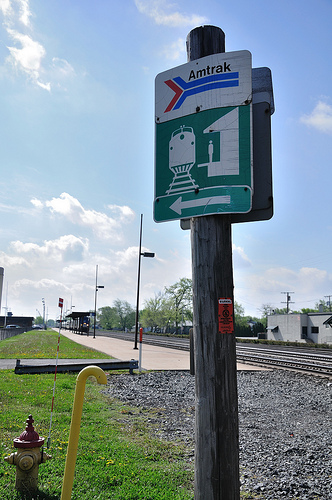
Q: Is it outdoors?
A: Yes, it is outdoors.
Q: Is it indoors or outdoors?
A: It is outdoors.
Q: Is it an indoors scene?
A: No, it is outdoors.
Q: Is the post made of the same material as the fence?
A: No, the post is made of wood and the fence is made of metal.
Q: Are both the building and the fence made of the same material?
A: No, the building is made of concrete and the fence is made of metal.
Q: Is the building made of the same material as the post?
A: No, the building is made of concrete and the post is made of wood.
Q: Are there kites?
A: No, there are no kites.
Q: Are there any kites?
A: No, there are no kites.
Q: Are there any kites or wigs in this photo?
A: No, there are no kites or wigs.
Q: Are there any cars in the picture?
A: No, there are no cars.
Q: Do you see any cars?
A: No, there are no cars.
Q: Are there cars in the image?
A: No, there are no cars.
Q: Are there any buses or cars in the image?
A: No, there are no cars or buses.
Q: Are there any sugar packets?
A: No, there are no sugar packets.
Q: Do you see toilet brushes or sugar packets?
A: No, there are no sugar packets or toilet brushes.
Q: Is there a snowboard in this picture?
A: No, there are no snowboards.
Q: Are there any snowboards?
A: No, there are no snowboards.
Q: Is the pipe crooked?
A: Yes, the pipe is crooked.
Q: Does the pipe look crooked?
A: Yes, the pipe is crooked.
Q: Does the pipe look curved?
A: Yes, the pipe is curved.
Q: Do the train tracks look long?
A: Yes, the train tracks are long.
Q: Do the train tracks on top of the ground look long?
A: Yes, the railroad tracks are long.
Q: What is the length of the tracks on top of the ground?
A: The tracks are long.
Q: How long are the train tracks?
A: The train tracks are long.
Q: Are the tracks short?
A: No, the tracks are long.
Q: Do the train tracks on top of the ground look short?
A: No, the train tracks are long.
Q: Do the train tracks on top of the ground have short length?
A: No, the train tracks are long.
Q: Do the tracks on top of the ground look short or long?
A: The tracks are long.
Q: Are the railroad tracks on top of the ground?
A: Yes, the railroad tracks are on top of the ground.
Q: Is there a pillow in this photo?
A: No, there are no pillows.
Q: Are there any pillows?
A: No, there are no pillows.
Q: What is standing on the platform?
A: The lamp post is standing on the platform.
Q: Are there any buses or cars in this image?
A: No, there are no cars or buses.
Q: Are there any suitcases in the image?
A: No, there are no suitcases.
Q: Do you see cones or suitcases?
A: No, there are no suitcases or cones.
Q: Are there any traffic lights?
A: No, there are no traffic lights.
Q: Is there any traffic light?
A: No, there are no traffic lights.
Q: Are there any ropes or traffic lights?
A: No, there are no traffic lights or ropes.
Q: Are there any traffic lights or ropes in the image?
A: No, there are no traffic lights or ropes.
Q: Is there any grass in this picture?
A: Yes, there is grass.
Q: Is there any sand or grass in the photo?
A: Yes, there is grass.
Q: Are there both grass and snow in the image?
A: No, there is grass but no snow.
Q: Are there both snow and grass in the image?
A: No, there is grass but no snow.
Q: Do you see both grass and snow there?
A: No, there is grass but no snow.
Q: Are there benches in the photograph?
A: No, there are no benches.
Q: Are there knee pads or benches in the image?
A: No, there are no benches or knee pads.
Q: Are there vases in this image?
A: No, there are no vases.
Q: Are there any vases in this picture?
A: No, there are no vases.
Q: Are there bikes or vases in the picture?
A: No, there are no vases or bikes.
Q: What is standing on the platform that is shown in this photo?
A: The street light is standing on the platform.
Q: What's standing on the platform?
A: The street light is standing on the platform.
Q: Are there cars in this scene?
A: No, there are no cars.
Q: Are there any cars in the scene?
A: No, there are no cars.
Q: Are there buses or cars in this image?
A: No, there are no cars or buses.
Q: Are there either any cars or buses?
A: No, there are no cars or buses.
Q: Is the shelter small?
A: Yes, the shelter is small.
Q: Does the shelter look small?
A: Yes, the shelter is small.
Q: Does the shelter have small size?
A: Yes, the shelter is small.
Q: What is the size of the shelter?
A: The shelter is small.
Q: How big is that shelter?
A: The shelter is small.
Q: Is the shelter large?
A: No, the shelter is small.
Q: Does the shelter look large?
A: No, the shelter is small.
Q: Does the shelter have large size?
A: No, the shelter is small.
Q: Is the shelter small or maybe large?
A: The shelter is small.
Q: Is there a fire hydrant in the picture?
A: Yes, there is a fire hydrant.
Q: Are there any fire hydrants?
A: Yes, there is a fire hydrant.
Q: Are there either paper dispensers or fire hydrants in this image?
A: Yes, there is a fire hydrant.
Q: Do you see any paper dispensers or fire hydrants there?
A: Yes, there is a fire hydrant.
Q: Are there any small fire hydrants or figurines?
A: Yes, there is a small fire hydrant.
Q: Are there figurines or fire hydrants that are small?
A: Yes, the fire hydrant is small.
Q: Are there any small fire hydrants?
A: Yes, there is a small fire hydrant.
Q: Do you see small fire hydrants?
A: Yes, there is a small fire hydrant.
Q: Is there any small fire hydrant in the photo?
A: Yes, there is a small fire hydrant.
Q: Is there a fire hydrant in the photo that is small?
A: Yes, there is a fire hydrant that is small.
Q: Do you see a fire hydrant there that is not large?
A: Yes, there is a small fire hydrant.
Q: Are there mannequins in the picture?
A: No, there are no mannequins.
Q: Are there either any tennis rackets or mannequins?
A: No, there are no mannequins or tennis rackets.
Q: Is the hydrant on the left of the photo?
A: Yes, the hydrant is on the left of the image.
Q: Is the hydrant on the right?
A: No, the hydrant is on the left of the image.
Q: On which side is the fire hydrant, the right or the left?
A: The fire hydrant is on the left of the image.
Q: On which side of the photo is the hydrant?
A: The hydrant is on the left of the image.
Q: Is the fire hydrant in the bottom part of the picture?
A: Yes, the fire hydrant is in the bottom of the image.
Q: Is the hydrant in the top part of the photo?
A: No, the hydrant is in the bottom of the image.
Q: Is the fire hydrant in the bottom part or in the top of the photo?
A: The fire hydrant is in the bottom of the image.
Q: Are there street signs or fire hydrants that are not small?
A: No, there is a fire hydrant but it is small.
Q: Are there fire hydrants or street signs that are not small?
A: No, there is a fire hydrant but it is small.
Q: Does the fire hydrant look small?
A: Yes, the fire hydrant is small.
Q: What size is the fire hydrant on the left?
A: The hydrant is small.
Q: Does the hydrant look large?
A: No, the hydrant is small.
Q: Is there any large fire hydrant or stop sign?
A: No, there is a fire hydrant but it is small.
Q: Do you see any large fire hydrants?
A: No, there is a fire hydrant but it is small.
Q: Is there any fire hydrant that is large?
A: No, there is a fire hydrant but it is small.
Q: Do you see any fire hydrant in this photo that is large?
A: No, there is a fire hydrant but it is small.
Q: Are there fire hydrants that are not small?
A: No, there is a fire hydrant but it is small.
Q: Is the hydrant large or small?
A: The hydrant is small.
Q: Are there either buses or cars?
A: No, there are no cars or buses.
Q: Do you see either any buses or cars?
A: No, there are no cars or buses.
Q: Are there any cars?
A: No, there are no cars.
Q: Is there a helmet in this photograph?
A: No, there are no helmets.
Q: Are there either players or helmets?
A: No, there are no helmets or players.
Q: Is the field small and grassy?
A: Yes, the field is small and grassy.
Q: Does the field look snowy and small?
A: No, the field is small but grassy.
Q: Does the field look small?
A: Yes, the field is small.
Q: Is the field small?
A: Yes, the field is small.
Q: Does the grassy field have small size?
A: Yes, the field is small.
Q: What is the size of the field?
A: The field is small.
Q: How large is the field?
A: The field is small.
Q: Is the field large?
A: No, the field is small.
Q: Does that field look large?
A: No, the field is small.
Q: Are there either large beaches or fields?
A: No, there is a field but it is small.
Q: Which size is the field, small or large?
A: The field is small.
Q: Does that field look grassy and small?
A: Yes, the field is grassy and small.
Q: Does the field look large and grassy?
A: No, the field is grassy but small.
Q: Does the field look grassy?
A: Yes, the field is grassy.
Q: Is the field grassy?
A: Yes, the field is grassy.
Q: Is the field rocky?
A: No, the field is grassy.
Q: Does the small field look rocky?
A: No, the field is grassy.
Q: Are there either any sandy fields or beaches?
A: No, there is a field but it is grassy.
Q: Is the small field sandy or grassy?
A: The field is grassy.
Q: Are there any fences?
A: Yes, there is a fence.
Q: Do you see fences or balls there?
A: Yes, there is a fence.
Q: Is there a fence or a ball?
A: Yes, there is a fence.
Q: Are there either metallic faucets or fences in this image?
A: Yes, there is a metal fence.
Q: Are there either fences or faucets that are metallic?
A: Yes, the fence is metallic.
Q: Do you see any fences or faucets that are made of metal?
A: Yes, the fence is made of metal.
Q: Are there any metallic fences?
A: Yes, there is a metal fence.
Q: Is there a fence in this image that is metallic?
A: Yes, there is a fence that is metallic.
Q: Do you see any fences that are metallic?
A: Yes, there is a fence that is metallic.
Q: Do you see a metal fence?
A: Yes, there is a fence that is made of metal.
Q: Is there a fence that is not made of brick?
A: Yes, there is a fence that is made of metal.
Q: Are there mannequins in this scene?
A: No, there are no mannequins.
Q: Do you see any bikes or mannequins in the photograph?
A: No, there are no mannequins or bikes.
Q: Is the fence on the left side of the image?
A: Yes, the fence is on the left of the image.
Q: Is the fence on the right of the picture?
A: No, the fence is on the left of the image.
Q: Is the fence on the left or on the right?
A: The fence is on the left of the image.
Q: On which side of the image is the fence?
A: The fence is on the left of the image.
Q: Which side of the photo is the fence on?
A: The fence is on the left of the image.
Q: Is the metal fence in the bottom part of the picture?
A: Yes, the fence is in the bottom of the image.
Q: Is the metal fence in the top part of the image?
A: No, the fence is in the bottom of the image.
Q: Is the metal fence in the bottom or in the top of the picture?
A: The fence is in the bottom of the image.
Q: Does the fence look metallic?
A: Yes, the fence is metallic.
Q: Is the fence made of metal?
A: Yes, the fence is made of metal.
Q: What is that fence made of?
A: The fence is made of metal.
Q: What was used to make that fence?
A: The fence is made of metal.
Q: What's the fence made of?
A: The fence is made of metal.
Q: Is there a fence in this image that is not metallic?
A: No, there is a fence but it is metallic.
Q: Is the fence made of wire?
A: No, the fence is made of metal.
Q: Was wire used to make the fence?
A: No, the fence is made of metal.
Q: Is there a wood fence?
A: No, there is a fence but it is made of metal.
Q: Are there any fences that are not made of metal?
A: No, there is a fence but it is made of metal.